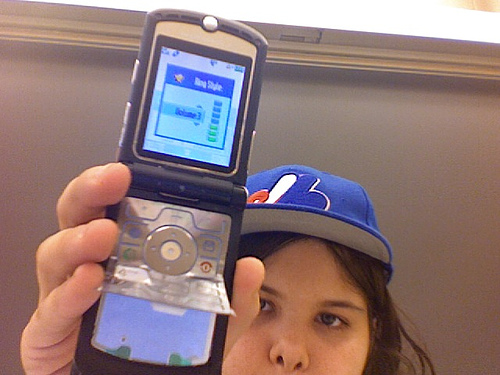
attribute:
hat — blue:
[241, 163, 392, 285]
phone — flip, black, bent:
[72, 7, 268, 374]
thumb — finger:
[224, 256, 267, 359]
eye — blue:
[319, 315, 338, 326]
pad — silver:
[95, 196, 238, 316]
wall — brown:
[3, 39, 496, 373]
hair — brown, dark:
[240, 231, 437, 373]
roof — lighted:
[1, 1, 496, 125]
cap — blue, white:
[242, 164, 394, 286]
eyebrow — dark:
[320, 299, 368, 313]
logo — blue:
[246, 173, 330, 214]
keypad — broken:
[90, 198, 234, 368]